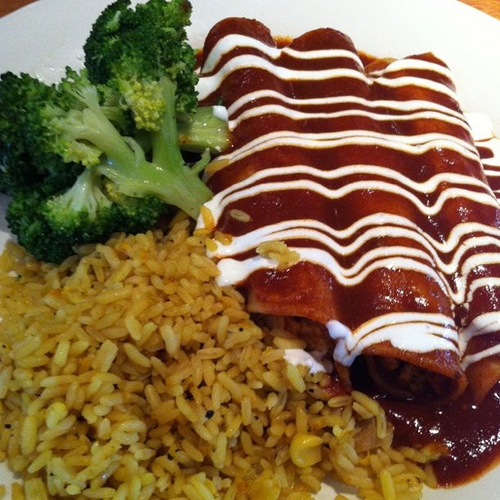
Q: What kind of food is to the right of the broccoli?
A: The food is Mexican food.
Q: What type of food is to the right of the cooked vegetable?
A: The food is Mexican food.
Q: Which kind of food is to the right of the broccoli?
A: The food is Mexican food.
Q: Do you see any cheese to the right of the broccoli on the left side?
A: No, there is Mexican food to the right of the broccoli.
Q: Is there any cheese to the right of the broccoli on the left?
A: No, there is Mexican food to the right of the broccoli.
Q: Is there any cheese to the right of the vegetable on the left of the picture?
A: No, there is Mexican food to the right of the broccoli.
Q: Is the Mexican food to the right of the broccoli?
A: Yes, the Mexican food is to the right of the broccoli.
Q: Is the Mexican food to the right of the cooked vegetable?
A: Yes, the Mexican food is to the right of the broccoli.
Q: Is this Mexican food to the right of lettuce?
A: No, the Mexican food is to the right of the broccoli.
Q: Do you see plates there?
A: Yes, there is a plate.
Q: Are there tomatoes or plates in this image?
A: Yes, there is a plate.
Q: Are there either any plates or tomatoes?
A: Yes, there is a plate.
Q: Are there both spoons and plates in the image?
A: No, there is a plate but no spoons.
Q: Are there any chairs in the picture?
A: No, there are no chairs.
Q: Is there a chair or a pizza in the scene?
A: No, there are no chairs or pizzas.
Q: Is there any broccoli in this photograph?
A: Yes, there is broccoli.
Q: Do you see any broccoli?
A: Yes, there is broccoli.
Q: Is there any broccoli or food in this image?
A: Yes, there is broccoli.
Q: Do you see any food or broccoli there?
A: Yes, there is broccoli.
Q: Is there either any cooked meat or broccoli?
A: Yes, there is cooked broccoli.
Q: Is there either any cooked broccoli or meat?
A: Yes, there is cooked broccoli.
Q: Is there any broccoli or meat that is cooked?
A: Yes, the broccoli is cooked.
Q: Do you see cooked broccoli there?
A: Yes, there is cooked broccoli.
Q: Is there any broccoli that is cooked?
A: Yes, there is broccoli that is cooked.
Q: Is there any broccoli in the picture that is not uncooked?
A: Yes, there is cooked broccoli.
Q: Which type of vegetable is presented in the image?
A: The vegetable is broccoli.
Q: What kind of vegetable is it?
A: The vegetable is broccoli.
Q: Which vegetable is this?
A: This is broccoli.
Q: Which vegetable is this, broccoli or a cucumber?
A: This is broccoli.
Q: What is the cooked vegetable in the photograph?
A: The vegetable is broccoli.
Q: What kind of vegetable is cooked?
A: The vegetable is broccoli.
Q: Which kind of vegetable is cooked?
A: The vegetable is broccoli.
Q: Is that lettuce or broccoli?
A: That is broccoli.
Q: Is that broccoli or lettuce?
A: That is broccoli.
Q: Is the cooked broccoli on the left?
A: Yes, the broccoli is on the left of the image.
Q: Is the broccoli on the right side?
A: No, the broccoli is on the left of the image.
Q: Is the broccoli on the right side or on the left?
A: The broccoli is on the left of the image.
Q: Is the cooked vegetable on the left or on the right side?
A: The broccoli is on the left of the image.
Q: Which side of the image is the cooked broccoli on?
A: The broccoli is on the left of the image.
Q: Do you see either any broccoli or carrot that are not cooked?
A: No, there is broccoli but it is cooked.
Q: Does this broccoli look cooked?
A: Yes, the broccoli is cooked.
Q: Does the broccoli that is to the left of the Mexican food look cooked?
A: Yes, the broccoli is cooked.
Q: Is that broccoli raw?
A: No, the broccoli is cooked.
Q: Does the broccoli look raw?
A: No, the broccoli is cooked.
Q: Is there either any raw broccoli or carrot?
A: No, there is broccoli but it is cooked.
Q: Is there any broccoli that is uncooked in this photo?
A: No, there is broccoli but it is cooked.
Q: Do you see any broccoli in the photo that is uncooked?
A: No, there is broccoli but it is cooked.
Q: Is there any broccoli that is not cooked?
A: No, there is broccoli but it is cooked.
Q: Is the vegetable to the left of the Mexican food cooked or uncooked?
A: The broccoli is cooked.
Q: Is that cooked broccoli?
A: Yes, that is cooked broccoli.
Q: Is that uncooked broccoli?
A: No, that is cooked broccoli.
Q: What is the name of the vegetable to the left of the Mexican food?
A: The vegetable is broccoli.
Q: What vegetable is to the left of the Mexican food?
A: The vegetable is broccoli.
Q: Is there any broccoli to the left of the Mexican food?
A: Yes, there is broccoli to the left of the Mexican food.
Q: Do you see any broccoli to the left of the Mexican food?
A: Yes, there is broccoli to the left of the Mexican food.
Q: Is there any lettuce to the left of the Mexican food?
A: No, there is broccoli to the left of the Mexican food.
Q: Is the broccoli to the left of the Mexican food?
A: Yes, the broccoli is to the left of the Mexican food.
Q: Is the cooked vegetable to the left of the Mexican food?
A: Yes, the broccoli is to the left of the Mexican food.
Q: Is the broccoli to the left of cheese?
A: No, the broccoli is to the left of the Mexican food.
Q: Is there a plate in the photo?
A: Yes, there is a plate.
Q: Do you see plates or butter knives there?
A: Yes, there is a plate.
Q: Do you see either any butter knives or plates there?
A: Yes, there is a plate.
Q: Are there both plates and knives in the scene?
A: No, there is a plate but no knives.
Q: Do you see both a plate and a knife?
A: No, there is a plate but no knives.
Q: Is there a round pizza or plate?
A: Yes, there is a round plate.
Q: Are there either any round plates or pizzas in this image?
A: Yes, there is a round plate.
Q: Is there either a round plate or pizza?
A: Yes, there is a round plate.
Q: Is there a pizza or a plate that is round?
A: Yes, the plate is round.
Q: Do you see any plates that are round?
A: Yes, there is a round plate.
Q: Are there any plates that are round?
A: Yes, there is a plate that is round.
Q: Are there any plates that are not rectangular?
A: Yes, there is a round plate.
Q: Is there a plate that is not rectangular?
A: Yes, there is a round plate.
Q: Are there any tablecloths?
A: No, there are no tablecloths.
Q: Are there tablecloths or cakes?
A: No, there are no tablecloths or cakes.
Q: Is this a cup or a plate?
A: This is a plate.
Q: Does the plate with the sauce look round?
A: Yes, the plate is round.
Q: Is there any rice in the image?
A: Yes, there is rice.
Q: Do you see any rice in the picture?
A: Yes, there is rice.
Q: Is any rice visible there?
A: Yes, there is rice.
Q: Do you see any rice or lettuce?
A: Yes, there is rice.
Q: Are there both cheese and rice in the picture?
A: No, there is rice but no cheese.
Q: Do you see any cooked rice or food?
A: Yes, there is cooked rice.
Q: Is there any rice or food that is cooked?
A: Yes, the rice is cooked.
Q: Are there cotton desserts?
A: No, there are no cotton desserts.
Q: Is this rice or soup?
A: This is rice.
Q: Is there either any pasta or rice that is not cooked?
A: No, there is rice but it is cooked.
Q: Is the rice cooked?
A: Yes, the rice is cooked.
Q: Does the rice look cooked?
A: Yes, the rice is cooked.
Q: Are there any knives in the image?
A: No, there are no knives.